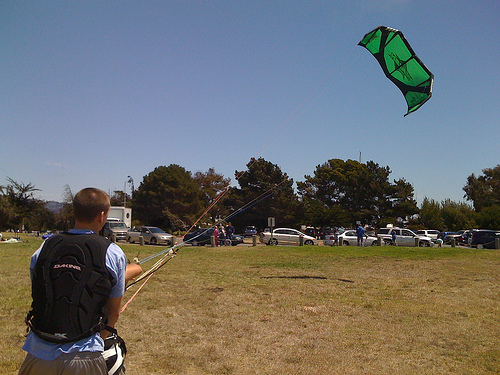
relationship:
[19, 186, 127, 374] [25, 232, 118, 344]
man wearing a chest protector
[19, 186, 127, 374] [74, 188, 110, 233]
man has a head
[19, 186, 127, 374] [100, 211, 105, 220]
man has an ear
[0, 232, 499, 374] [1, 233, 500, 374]
grass on ground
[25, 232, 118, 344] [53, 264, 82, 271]
chest protector has lettering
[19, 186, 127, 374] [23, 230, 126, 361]
man wearing a shirt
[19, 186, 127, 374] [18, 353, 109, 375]
man wearing shorts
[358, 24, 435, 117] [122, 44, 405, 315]
kite has strings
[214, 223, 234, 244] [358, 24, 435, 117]
family watching kite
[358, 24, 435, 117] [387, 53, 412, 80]
kite has a design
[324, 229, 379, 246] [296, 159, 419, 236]
car near tree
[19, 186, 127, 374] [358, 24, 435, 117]
man flying kite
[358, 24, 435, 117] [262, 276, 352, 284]
kite has a shadow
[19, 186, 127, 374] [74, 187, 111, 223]
man has blonde hair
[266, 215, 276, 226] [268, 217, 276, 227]
back of a sign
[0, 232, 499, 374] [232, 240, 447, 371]
grass on ground